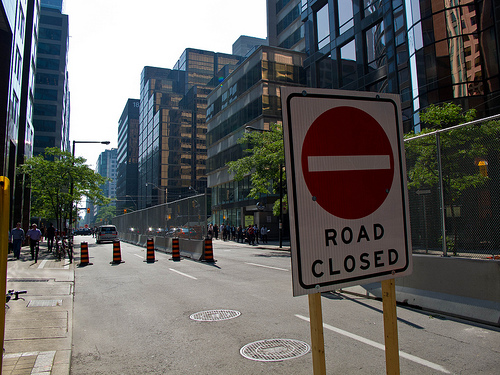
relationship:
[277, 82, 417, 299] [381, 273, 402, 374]
sign on pole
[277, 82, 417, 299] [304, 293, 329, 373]
sign on pole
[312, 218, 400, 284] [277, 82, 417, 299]
writing on sign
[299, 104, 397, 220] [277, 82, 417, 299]
circle on sign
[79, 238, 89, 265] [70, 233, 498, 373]
cone in road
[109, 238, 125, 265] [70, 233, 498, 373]
cone in road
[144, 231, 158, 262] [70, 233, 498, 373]
cone in road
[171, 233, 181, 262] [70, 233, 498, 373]
cone in road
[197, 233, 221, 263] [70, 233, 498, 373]
barrel in road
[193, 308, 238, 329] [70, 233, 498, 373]
cover on road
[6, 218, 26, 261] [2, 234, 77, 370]
men walking on sidewalk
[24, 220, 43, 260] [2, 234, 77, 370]
men walking on sidewalk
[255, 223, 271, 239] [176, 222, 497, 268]
people on sidewalk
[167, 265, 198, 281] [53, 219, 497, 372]
lane marker painted on street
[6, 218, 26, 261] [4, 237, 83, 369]
men walking on sidewalk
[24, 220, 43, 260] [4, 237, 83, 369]
men walking on sidewalk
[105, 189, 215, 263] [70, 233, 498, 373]
fence near center of road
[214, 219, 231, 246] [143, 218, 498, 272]
people on sidewalk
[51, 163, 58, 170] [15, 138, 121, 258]
leaves on tree